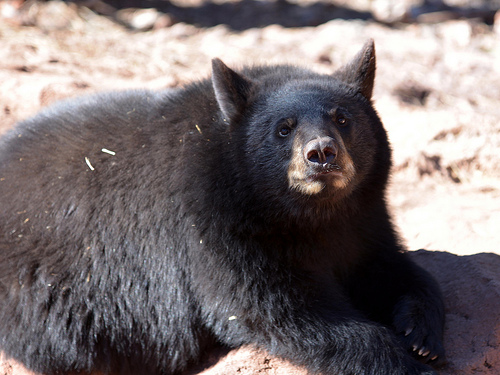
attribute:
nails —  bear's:
[402, 328, 438, 361]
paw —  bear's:
[395, 302, 447, 365]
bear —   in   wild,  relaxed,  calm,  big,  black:
[4, 41, 461, 367]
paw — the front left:
[369, 313, 480, 374]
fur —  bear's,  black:
[87, 218, 194, 370]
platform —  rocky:
[1, 248, 499, 372]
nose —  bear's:
[297, 122, 350, 187]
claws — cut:
[402, 322, 440, 367]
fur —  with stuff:
[23, 137, 165, 220]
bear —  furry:
[0, 77, 441, 368]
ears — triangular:
[332, 37, 374, 102]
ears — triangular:
[212, 56, 257, 126]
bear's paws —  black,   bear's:
[322, 275, 457, 374]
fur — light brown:
[21, 39, 458, 373]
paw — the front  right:
[343, 326, 416, 373]